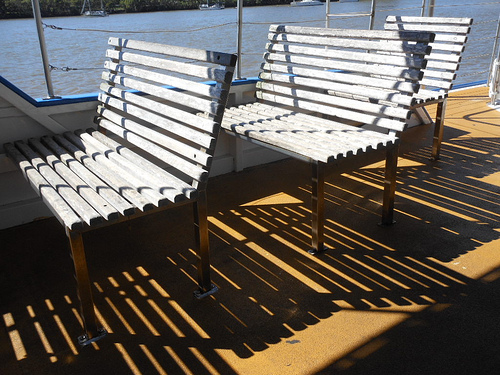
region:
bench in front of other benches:
[5, 32, 245, 351]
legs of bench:
[57, 190, 228, 353]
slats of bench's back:
[95, 38, 240, 180]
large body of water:
[0, 5, 498, 102]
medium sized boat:
[72, 2, 109, 17]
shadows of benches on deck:
[16, 155, 496, 370]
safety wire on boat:
[31, 15, 391, 36]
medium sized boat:
[188, 1, 223, 9]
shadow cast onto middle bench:
[396, 18, 439, 85]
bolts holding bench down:
[74, 324, 112, 347]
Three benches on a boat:
[26, 5, 488, 282]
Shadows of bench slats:
[98, 284, 238, 374]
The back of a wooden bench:
[69, 15, 241, 194]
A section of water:
[53, 22, 93, 71]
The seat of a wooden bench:
[3, 113, 185, 249]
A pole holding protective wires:
[21, 2, 88, 114]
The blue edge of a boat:
[4, 64, 90, 125]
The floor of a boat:
[310, 255, 429, 368]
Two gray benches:
[234, 4, 482, 257]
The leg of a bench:
[294, 177, 356, 269]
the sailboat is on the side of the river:
[76, 0, 108, 18]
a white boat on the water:
[288, 0, 325, 8]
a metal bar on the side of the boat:
[26, 0, 60, 102]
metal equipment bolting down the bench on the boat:
[188, 288, 219, 305]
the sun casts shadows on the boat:
[196, 200, 498, 325]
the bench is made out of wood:
[11, 33, 249, 353]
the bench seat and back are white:
[1, 35, 238, 232]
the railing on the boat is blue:
[1, 73, 97, 105]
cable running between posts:
[41, 20, 234, 36]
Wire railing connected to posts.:
[26, 33, 83, 91]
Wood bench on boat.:
[58, 145, 181, 301]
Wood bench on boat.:
[252, 30, 353, 323]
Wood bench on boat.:
[435, 77, 460, 154]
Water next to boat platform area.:
[8, 43, 44, 70]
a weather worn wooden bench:
[5, 33, 232, 346]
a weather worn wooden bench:
[211, 21, 436, 255]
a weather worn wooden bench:
[381, 13, 468, 171]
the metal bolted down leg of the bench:
[65, 227, 110, 347]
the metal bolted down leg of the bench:
[193, 194, 215, 299]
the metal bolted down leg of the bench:
[306, 163, 326, 258]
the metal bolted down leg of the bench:
[380, 146, 399, 241]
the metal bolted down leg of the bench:
[430, 93, 450, 175]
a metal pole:
[29, 2, 57, 100]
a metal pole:
[233, 1, 248, 80]